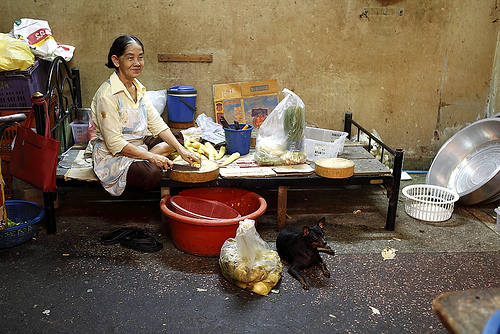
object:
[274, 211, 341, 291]
dog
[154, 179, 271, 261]
basins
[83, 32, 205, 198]
woman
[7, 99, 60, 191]
purse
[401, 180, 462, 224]
basket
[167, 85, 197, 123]
water jug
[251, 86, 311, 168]
bag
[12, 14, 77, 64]
bag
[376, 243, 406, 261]
debris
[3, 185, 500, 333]
ground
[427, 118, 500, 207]
bowl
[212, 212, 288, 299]
bag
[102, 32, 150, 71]
hair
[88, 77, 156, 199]
apron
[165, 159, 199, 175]
knife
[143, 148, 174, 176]
lady's hand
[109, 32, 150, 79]
head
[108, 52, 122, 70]
ear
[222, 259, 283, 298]
yellowy substance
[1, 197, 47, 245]
container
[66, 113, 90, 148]
crate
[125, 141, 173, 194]
pants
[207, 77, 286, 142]
oatmeal box